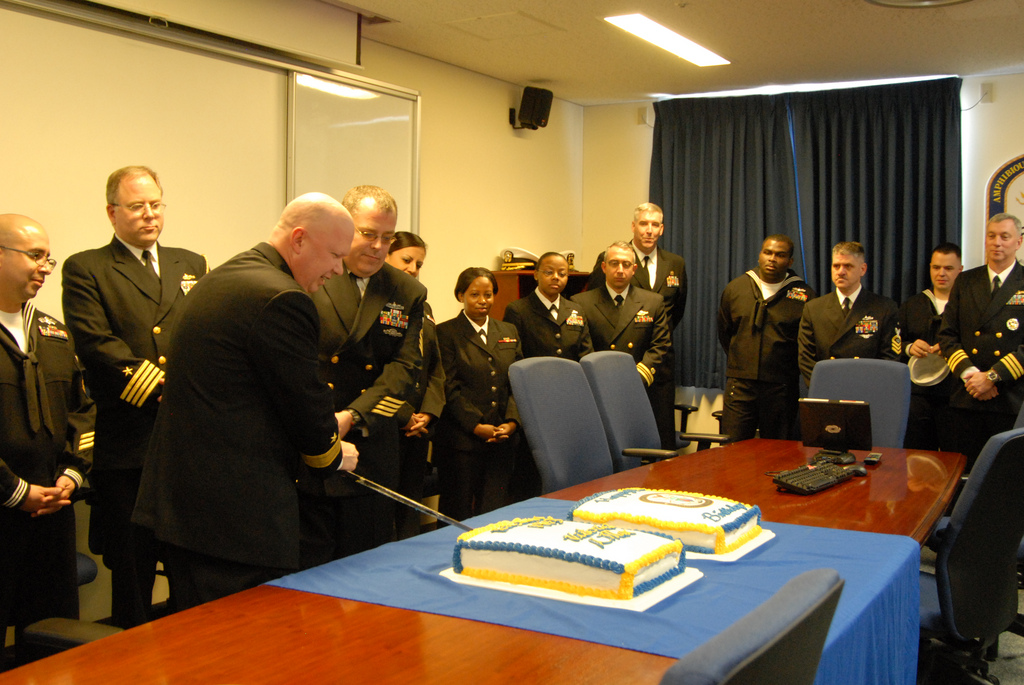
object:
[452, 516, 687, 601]
cake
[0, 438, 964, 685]
table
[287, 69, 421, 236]
board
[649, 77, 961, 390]
curtains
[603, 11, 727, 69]
light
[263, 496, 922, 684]
cloth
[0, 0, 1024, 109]
ceiling